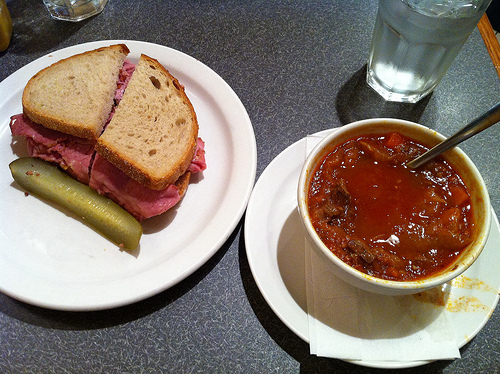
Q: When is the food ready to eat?
A: Now.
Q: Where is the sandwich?
A: On the plate.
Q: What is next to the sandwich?
A: Pickle.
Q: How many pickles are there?
A: One.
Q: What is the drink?
A: Water.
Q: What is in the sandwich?
A: Meat.